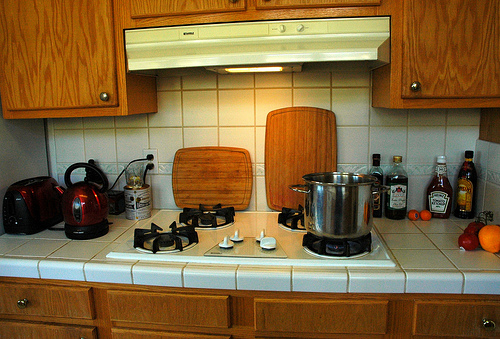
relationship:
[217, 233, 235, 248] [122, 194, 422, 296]
knob on surface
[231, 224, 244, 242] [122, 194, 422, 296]
knob on surface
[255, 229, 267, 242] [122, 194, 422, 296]
knob on surface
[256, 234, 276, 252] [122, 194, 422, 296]
knob on surface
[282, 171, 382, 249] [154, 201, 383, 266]
pot on stove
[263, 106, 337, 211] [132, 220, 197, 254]
board behind stove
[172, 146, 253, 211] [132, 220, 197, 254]
board behind stove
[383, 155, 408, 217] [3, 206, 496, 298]
olive oil on counter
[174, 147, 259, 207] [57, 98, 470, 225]
board standing against wall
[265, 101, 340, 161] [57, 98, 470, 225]
board standing against wall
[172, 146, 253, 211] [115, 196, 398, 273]
board behind stove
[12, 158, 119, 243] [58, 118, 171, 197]
appliances plugged into wall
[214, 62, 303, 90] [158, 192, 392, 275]
lights above stove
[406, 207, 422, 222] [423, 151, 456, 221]
tangerine between bottle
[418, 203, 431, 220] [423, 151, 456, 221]
tangerine between bottle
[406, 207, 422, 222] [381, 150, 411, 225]
tangerine between bottle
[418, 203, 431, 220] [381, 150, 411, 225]
tangerine between bottle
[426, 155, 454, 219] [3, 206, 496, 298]
bottle on counter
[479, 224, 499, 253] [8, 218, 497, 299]
orange on counter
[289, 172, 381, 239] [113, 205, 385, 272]
pot on stove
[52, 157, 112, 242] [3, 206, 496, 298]
kettle on counter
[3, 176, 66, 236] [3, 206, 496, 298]
toaster on counter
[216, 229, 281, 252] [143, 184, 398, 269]
knob for burners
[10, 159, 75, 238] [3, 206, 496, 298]
toaster on counter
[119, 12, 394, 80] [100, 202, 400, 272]
hood above stove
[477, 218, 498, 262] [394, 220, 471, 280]
orange on counter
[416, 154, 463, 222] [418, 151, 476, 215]
bottle of ketchup